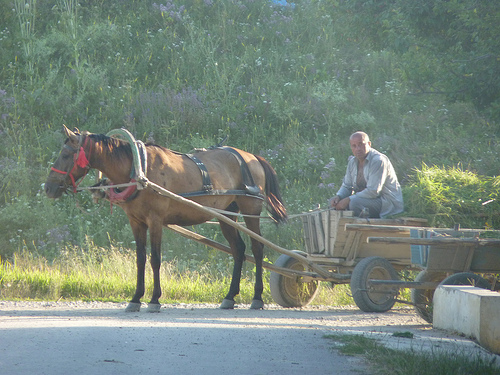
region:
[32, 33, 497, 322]
a horse pulling buggie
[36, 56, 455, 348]
a horse pulling a buggy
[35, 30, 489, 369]
a horse pulling a cart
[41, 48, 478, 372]
a horse pulling a man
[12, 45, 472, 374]
a brown horse pulling a buggy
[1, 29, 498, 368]
a brown horse pulling a buggie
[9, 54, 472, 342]
a brown horse pulling a cart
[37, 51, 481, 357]
a brown horse pulling a man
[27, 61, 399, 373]
a brown horse on the road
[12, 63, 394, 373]
a horse on the road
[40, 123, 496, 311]
horse, cart and driver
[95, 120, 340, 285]
thick yoke attached to horse and cart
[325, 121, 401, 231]
driver leaning forward while seated in cart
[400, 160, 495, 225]
green grasses piled in back of cart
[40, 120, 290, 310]
harnessed brown horse moving tail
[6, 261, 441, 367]
horse standing on flat tan ground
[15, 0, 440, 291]
slope filled with purple, blue and white flowers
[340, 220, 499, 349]
smaller cart next to cement block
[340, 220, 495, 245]
two long poles forming top of smaller cart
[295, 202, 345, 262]
front of large cart made of wood planks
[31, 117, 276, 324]
A horse that is standing.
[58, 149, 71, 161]
A horse eye that is open.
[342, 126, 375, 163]
A man with his face looking sideways.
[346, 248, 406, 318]
A wheel on a wagon.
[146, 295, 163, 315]
A horse's hoof on the ground.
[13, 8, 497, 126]
Green trees and bushes outside.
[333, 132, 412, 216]
A man sitting on a wagon.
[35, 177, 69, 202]
A horse's mouth closed.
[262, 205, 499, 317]
A wagon carrying a man.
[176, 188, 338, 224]
Rope is tide to a horse.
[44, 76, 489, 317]
a horse pulling a wagon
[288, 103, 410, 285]
a man sitting in a wagon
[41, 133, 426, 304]
a brown horse pulling a wagon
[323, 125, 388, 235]
a man with a unbuttoned shirt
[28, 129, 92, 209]
a horse wearing a red bridle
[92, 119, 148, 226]
a horse wearing a harness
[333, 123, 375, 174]
a man with no hair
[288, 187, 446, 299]
a wood wagon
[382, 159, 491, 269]
green grass in a wagon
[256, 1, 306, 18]
a patch of blue wildflowers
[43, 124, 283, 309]
a standing brown horse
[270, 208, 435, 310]
a wooden wagon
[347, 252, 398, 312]
a wagon front tire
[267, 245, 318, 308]
a wagon front tire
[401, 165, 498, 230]
a green bale of grass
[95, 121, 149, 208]
a white and red harness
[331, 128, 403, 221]
a seated man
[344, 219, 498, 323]
a wooden push wagon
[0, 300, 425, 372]
a gravel paved road